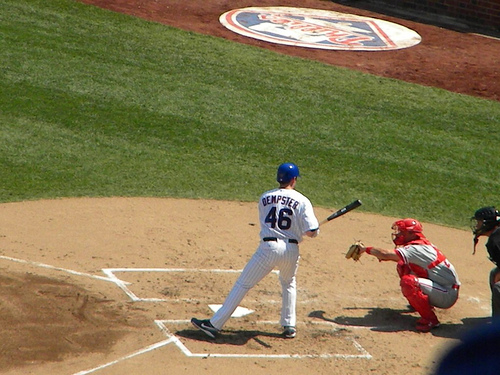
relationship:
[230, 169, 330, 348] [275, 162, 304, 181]
batter wearing helmet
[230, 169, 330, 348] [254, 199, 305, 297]
batter wearing jersey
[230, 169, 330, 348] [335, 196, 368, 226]
batter holding bat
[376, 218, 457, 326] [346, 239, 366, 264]
catcher holding mitt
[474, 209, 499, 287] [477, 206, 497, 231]
umpire wearing hat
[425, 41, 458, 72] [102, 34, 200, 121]
dirt near grass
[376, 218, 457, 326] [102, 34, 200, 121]
catcher on grass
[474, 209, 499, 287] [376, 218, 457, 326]
umpire behind catcher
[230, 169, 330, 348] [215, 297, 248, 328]
batter at plate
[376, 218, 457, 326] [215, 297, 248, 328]
catcher behind plate